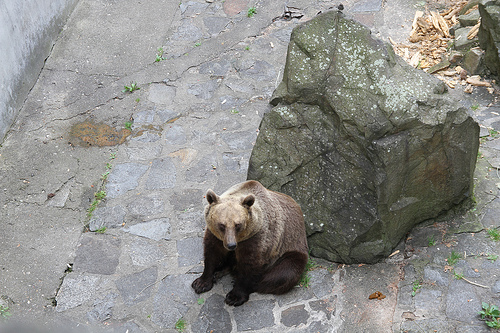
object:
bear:
[189, 175, 312, 309]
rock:
[243, 7, 481, 269]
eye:
[212, 225, 229, 236]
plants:
[440, 250, 464, 271]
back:
[243, 174, 287, 215]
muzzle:
[213, 220, 245, 252]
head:
[199, 197, 266, 252]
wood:
[426, 7, 453, 41]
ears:
[204, 188, 221, 202]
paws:
[216, 288, 248, 306]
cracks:
[50, 0, 188, 313]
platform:
[0, 0, 499, 332]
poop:
[71, 116, 134, 150]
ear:
[239, 191, 264, 210]